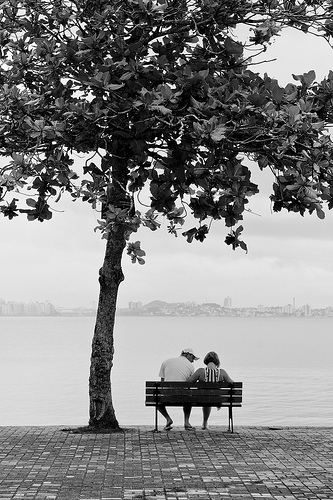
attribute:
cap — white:
[180, 349, 201, 363]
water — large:
[1, 316, 332, 429]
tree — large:
[0, 0, 333, 428]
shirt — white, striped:
[201, 368, 226, 383]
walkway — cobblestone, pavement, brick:
[4, 429, 333, 498]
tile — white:
[44, 479, 52, 485]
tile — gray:
[110, 451, 119, 458]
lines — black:
[198, 365, 224, 386]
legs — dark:
[152, 405, 239, 435]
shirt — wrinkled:
[159, 356, 195, 385]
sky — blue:
[0, 0, 331, 311]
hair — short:
[201, 352, 222, 369]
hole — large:
[70, 423, 133, 435]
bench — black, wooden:
[142, 381, 243, 407]